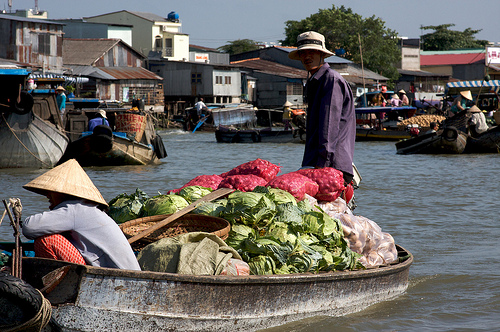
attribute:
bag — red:
[272, 171, 320, 202]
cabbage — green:
[228, 192, 271, 226]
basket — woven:
[121, 212, 231, 249]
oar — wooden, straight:
[125, 185, 235, 243]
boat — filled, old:
[5, 237, 413, 331]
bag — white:
[319, 199, 399, 264]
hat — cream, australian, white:
[289, 32, 334, 59]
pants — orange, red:
[34, 233, 85, 265]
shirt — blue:
[304, 62, 356, 183]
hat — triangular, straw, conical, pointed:
[24, 158, 110, 208]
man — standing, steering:
[290, 31, 356, 201]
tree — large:
[280, 5, 401, 90]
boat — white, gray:
[2, 109, 68, 170]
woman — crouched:
[22, 156, 143, 273]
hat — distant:
[398, 90, 404, 93]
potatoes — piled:
[398, 114, 446, 131]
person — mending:
[168, 10, 179, 22]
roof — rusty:
[95, 66, 162, 80]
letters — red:
[118, 115, 144, 132]